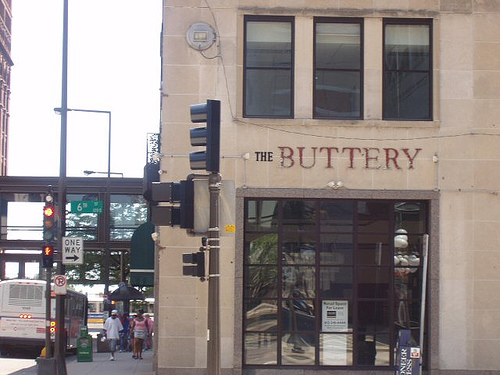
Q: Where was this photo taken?
A: On a street corner.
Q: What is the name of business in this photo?
A: The Buttery.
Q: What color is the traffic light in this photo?
A: Red.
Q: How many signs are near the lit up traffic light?
A: Three.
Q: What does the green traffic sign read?
A: 6th.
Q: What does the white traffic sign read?
A: ONE WAY.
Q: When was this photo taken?
A: Outside, during the daytime.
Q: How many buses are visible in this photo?
A: One.